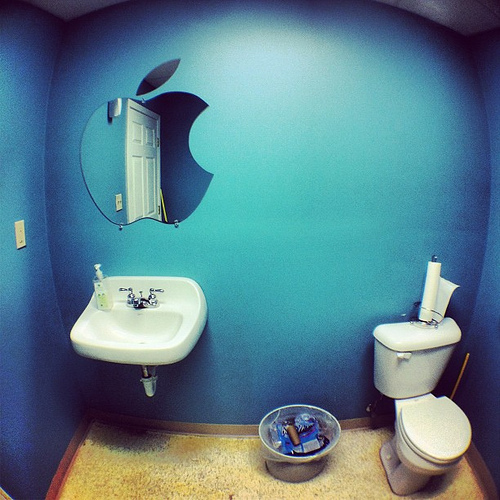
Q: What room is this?
A: Bathroom.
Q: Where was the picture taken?
A: In a bathroom.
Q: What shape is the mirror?
A: A apple.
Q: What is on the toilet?
A: Paper towels.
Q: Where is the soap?
A: On sink.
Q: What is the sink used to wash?
A: Hands.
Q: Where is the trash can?
A: On floor.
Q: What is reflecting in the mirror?
A: A door.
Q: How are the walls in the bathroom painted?
A: Blue.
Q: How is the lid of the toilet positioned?
A: Closed.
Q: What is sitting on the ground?
A: A trash can.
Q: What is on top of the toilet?
A: Paper towels.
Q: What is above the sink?
A: A mirror.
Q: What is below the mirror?
A: A sink.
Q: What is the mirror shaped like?
A: An apple.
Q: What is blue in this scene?
A: The walls.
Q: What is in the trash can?
A: Bag full of trash.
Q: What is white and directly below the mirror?
A: The sink.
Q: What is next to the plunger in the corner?
A: The white toilet.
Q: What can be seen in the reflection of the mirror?
A: The door.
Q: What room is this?
A: Bathroom.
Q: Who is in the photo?
A: Nobody.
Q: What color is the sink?
A: White.